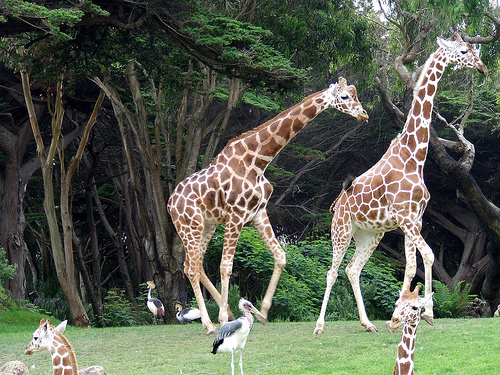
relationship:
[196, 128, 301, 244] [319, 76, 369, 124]
giraffe has head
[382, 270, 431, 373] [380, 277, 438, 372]
giraffe has head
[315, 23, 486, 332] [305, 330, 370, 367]
giraffe walking on grass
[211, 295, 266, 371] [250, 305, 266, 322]
bird has beak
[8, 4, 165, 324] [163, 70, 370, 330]
trees near a giraffe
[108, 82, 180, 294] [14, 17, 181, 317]
bark on tree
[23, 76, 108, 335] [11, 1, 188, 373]
bar of tree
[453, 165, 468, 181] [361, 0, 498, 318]
bark of tree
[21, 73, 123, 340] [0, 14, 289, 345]
limbs of tree